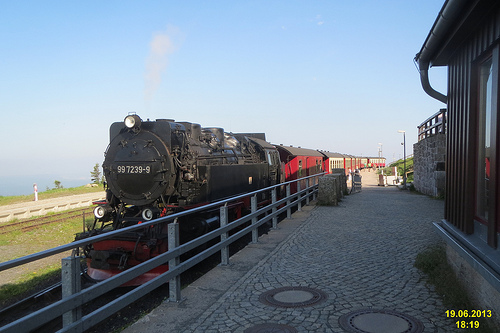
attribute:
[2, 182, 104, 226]
road — side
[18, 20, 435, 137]
sky — blue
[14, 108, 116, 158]
clouds — white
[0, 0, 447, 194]
sky — blue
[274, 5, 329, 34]
clouds — white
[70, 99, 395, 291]
train — black, red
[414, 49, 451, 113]
pipe — gutter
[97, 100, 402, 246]
train — white, red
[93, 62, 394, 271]
train — red, white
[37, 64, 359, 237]
train — red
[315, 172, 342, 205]
block — large concrete 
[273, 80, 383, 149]
clouds — white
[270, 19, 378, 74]
sky — blue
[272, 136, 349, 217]
car — red passenger train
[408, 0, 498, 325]
building —  front 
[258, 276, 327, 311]
designs — circular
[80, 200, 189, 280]
engine — train